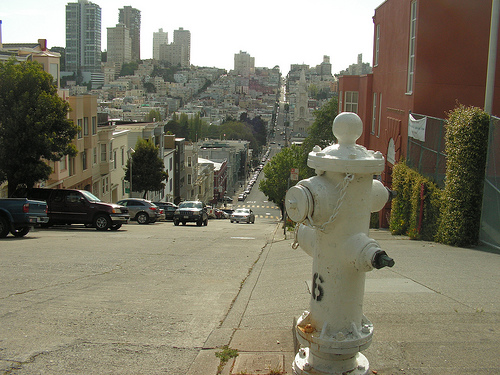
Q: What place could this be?
A: It is a city.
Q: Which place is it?
A: It is a city.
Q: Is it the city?
A: Yes, it is the city.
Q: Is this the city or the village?
A: It is the city.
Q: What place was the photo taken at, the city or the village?
A: It was taken at the city.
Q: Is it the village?
A: No, it is the city.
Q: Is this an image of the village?
A: No, the picture is showing the city.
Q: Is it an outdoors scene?
A: Yes, it is outdoors.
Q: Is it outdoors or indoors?
A: It is outdoors.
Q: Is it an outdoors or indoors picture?
A: It is outdoors.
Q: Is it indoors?
A: No, it is outdoors.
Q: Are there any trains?
A: No, there are no trains.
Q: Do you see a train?
A: No, there are no trains.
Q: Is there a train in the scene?
A: No, there are no trains.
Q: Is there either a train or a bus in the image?
A: No, there are no trains or buses.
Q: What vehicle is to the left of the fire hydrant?
A: The vehicle is a car.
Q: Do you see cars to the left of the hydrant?
A: Yes, there is a car to the left of the hydrant.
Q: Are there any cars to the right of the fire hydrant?
A: No, the car is to the left of the fire hydrant.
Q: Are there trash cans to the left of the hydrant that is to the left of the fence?
A: No, there is a car to the left of the hydrant.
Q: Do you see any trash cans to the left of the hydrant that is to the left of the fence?
A: No, there is a car to the left of the hydrant.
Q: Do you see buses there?
A: No, there are no buses.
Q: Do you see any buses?
A: No, there are no buses.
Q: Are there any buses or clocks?
A: No, there are no buses or clocks.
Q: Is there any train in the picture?
A: No, there are no trains.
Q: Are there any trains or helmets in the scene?
A: No, there are no trains or helmets.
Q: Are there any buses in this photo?
A: No, there are no buses.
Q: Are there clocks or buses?
A: No, there are no buses or clocks.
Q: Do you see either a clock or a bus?
A: No, there are no buses or clocks.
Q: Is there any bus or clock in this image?
A: No, there are no buses or clocks.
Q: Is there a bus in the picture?
A: No, there are no buses.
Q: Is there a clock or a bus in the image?
A: No, there are no buses or clocks.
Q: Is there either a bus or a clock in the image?
A: No, there are no buses or clocks.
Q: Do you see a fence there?
A: Yes, there is a fence.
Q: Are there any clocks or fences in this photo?
A: Yes, there is a fence.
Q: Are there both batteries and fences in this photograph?
A: No, there is a fence but no batteries.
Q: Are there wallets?
A: No, there are no wallets.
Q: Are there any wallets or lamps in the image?
A: No, there are no wallets or lamps.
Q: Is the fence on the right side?
A: Yes, the fence is on the right of the image.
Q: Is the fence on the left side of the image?
A: No, the fence is on the right of the image.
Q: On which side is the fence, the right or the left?
A: The fence is on the right of the image.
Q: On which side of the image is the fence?
A: The fence is on the right of the image.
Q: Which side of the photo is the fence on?
A: The fence is on the right of the image.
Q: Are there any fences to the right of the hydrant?
A: Yes, there is a fence to the right of the hydrant.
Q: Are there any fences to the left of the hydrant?
A: No, the fence is to the right of the hydrant.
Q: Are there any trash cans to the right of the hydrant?
A: No, there is a fence to the right of the hydrant.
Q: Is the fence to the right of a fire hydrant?
A: Yes, the fence is to the right of a fire hydrant.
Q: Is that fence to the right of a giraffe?
A: No, the fence is to the right of a fire hydrant.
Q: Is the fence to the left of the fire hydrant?
A: No, the fence is to the right of the fire hydrant.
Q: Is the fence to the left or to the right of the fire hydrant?
A: The fence is to the right of the fire hydrant.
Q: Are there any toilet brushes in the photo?
A: No, there are no toilet brushes.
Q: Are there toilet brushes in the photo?
A: No, there are no toilet brushes.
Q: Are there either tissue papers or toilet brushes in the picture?
A: No, there are no toilet brushes or tissue papers.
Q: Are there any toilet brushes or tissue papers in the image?
A: No, there are no toilet brushes or tissue papers.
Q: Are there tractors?
A: No, there are no tractors.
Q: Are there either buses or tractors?
A: No, there are no tractors or buses.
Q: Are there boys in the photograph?
A: No, there are no boys.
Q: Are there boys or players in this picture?
A: No, there are no boys or players.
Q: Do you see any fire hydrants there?
A: Yes, there is a fire hydrant.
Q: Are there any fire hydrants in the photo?
A: Yes, there is a fire hydrant.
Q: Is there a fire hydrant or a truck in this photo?
A: Yes, there is a fire hydrant.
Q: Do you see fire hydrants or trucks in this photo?
A: Yes, there is a fire hydrant.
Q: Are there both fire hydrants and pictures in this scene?
A: No, there is a fire hydrant but no pictures.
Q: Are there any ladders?
A: No, there are no ladders.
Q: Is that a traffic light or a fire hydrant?
A: That is a fire hydrant.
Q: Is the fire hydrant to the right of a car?
A: Yes, the fire hydrant is to the right of a car.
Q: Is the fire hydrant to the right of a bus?
A: No, the fire hydrant is to the right of a car.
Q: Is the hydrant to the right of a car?
A: Yes, the hydrant is to the right of a car.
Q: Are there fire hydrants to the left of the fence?
A: Yes, there is a fire hydrant to the left of the fence.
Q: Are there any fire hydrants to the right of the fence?
A: No, the fire hydrant is to the left of the fence.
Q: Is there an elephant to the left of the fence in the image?
A: No, there is a fire hydrant to the left of the fence.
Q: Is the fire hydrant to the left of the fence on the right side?
A: Yes, the fire hydrant is to the left of the fence.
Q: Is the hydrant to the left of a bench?
A: No, the hydrant is to the left of the fence.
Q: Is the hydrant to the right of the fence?
A: No, the hydrant is to the left of the fence.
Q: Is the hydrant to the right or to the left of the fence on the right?
A: The hydrant is to the left of the fence.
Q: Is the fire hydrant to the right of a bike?
A: No, the fire hydrant is to the right of a car.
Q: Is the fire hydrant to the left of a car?
A: No, the fire hydrant is to the right of a car.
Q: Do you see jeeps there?
A: No, there are no jeeps.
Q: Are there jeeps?
A: No, there are no jeeps.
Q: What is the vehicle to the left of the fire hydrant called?
A: The vehicle is a car.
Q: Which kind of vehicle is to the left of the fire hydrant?
A: The vehicle is a car.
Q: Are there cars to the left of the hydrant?
A: Yes, there is a car to the left of the hydrant.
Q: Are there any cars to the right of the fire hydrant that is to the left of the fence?
A: No, the car is to the left of the hydrant.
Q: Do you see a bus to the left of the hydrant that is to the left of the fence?
A: No, there is a car to the left of the hydrant.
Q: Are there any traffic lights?
A: No, there are no traffic lights.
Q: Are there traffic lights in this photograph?
A: No, there are no traffic lights.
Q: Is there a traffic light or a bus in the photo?
A: No, there are no traffic lights or buses.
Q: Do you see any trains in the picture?
A: No, there are no trains.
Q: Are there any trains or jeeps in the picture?
A: No, there are no trains or jeeps.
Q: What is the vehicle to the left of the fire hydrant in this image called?
A: The vehicle is a car.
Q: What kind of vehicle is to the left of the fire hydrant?
A: The vehicle is a car.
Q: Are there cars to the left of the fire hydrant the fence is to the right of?
A: Yes, there is a car to the left of the fire hydrant.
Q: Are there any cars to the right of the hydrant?
A: No, the car is to the left of the hydrant.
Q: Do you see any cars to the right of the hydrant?
A: No, the car is to the left of the hydrant.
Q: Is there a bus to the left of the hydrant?
A: No, there is a car to the left of the hydrant.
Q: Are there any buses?
A: No, there are no buses.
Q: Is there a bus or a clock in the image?
A: No, there are no buses or clocks.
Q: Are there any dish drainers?
A: No, there are no dish drainers.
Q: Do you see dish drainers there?
A: No, there are no dish drainers.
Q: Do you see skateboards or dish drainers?
A: No, there are no dish drainers or skateboards.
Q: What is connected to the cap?
A: The chain is connected to the cap.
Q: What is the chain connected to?
A: The chain is connected to the cap.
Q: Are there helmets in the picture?
A: No, there are no helmets.